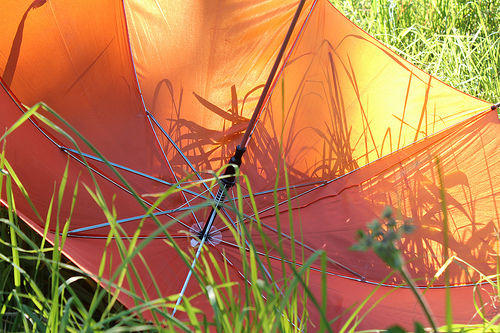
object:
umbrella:
[0, 26, 464, 318]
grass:
[391, 11, 497, 85]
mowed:
[411, 6, 486, 102]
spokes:
[111, 129, 354, 283]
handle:
[204, 0, 313, 199]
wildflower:
[348, 208, 449, 330]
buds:
[347, 201, 416, 268]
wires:
[65, 126, 383, 294]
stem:
[225, 143, 247, 187]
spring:
[217, 186, 226, 205]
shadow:
[211, 43, 422, 164]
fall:
[16, 264, 462, 326]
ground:
[9, 162, 482, 332]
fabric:
[169, 18, 247, 87]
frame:
[55, 107, 344, 299]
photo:
[0, 2, 495, 330]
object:
[225, 75, 265, 197]